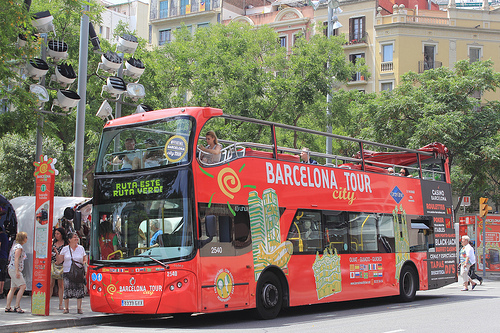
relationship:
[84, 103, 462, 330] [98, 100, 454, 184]
bus open top deck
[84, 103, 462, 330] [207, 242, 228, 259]
bus written 2540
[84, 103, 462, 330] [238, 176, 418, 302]
bus has picture of buildings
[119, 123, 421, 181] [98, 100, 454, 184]
passengers on  top deck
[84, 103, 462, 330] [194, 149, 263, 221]
bus has picture of sun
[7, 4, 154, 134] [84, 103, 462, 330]
street light behind bus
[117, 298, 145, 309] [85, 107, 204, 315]
license plate on front of bus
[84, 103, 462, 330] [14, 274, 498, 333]
bus on street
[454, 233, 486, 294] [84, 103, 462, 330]
woman walking behind bus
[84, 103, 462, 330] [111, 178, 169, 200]
bus has green letters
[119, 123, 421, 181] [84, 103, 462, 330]
passengers on top of bus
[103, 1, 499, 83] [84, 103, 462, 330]
buildings behind bus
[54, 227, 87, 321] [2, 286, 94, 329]
women standing on sidewalk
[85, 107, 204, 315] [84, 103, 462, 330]
screen on front of bus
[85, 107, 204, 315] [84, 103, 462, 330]
windshield on a bus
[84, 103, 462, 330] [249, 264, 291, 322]
bus has front wheel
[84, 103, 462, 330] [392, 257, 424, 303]
bus has rear wheel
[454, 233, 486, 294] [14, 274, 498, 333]
women walking across street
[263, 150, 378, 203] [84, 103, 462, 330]
words on side bus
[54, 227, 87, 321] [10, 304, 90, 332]
woman near a curb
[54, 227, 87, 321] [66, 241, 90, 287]
"woman with bag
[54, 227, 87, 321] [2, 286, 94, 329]
woman on sidewalk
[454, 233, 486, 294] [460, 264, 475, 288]
woman has tan pants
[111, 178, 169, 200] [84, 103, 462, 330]
text on front bus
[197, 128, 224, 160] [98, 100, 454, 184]
woman sitting on upper level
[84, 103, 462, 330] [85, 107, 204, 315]
bus has windshield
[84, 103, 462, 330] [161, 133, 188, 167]
bus has top sign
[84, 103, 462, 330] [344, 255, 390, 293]
bus has flag designs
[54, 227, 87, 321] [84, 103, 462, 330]
people getting on bus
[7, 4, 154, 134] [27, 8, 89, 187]
lights on poles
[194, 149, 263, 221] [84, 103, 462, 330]
design on bus